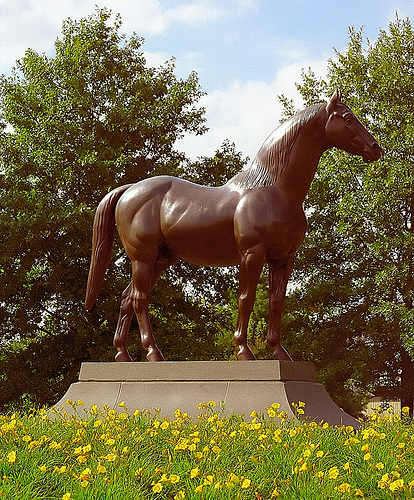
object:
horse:
[82, 91, 383, 363]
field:
[0, 396, 414, 500]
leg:
[234, 253, 286, 366]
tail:
[84, 173, 133, 312]